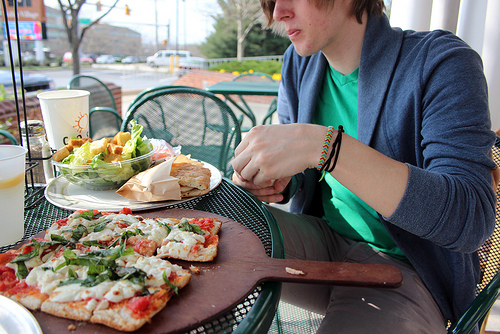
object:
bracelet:
[316, 122, 334, 174]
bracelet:
[320, 123, 344, 174]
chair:
[121, 87, 244, 183]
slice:
[131, 260, 186, 307]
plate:
[40, 151, 230, 214]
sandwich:
[117, 153, 213, 203]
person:
[225, 0, 495, 334]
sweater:
[271, 24, 498, 315]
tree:
[57, 0, 119, 97]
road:
[32, 58, 214, 91]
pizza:
[0, 208, 223, 330]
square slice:
[159, 212, 223, 260]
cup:
[34, 87, 91, 152]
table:
[226, 196, 258, 218]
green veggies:
[65, 237, 134, 278]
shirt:
[312, 55, 408, 257]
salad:
[46, 121, 156, 191]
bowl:
[49, 134, 156, 189]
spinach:
[76, 216, 106, 232]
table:
[3, 134, 276, 332]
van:
[143, 48, 212, 69]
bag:
[117, 157, 183, 204]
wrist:
[314, 124, 347, 179]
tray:
[2, 206, 406, 334]